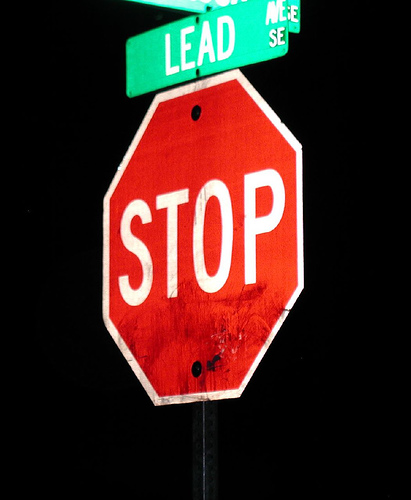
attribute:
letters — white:
[162, 15, 234, 76]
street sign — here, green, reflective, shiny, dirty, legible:
[125, 2, 290, 101]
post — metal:
[191, 400, 218, 499]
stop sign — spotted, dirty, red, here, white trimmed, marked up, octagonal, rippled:
[101, 68, 303, 407]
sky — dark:
[0, 1, 409, 498]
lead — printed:
[164, 17, 234, 75]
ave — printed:
[265, 0, 288, 26]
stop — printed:
[119, 170, 285, 307]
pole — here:
[188, 403, 216, 497]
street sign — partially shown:
[125, 0, 301, 34]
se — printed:
[268, 29, 285, 48]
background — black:
[0, 1, 408, 498]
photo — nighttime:
[0, 1, 407, 499]